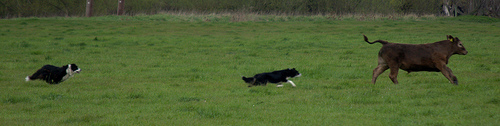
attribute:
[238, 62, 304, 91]
dog — small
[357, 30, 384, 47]
cow tail — long, brown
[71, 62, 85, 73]
face — black , white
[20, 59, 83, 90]
dog — black , white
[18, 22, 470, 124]
field — green, grassy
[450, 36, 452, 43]
tag — yellow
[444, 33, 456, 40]
ear — cows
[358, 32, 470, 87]
cow — large 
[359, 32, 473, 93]
animal — large 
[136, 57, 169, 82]
grass — green 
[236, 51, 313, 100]
dog — black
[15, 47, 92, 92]
dog — black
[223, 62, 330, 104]
cat —  running